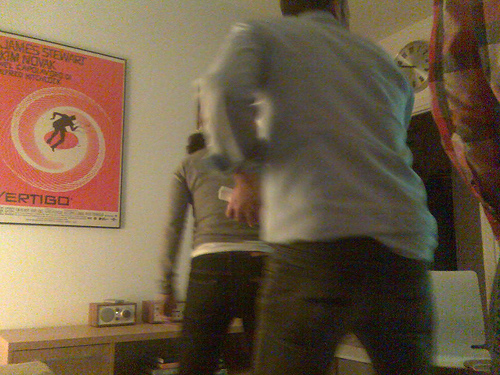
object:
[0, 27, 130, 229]
picture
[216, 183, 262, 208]
controller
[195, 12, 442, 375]
man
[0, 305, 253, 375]
desk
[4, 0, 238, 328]
wall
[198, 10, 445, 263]
shirt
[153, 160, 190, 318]
arm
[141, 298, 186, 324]
radio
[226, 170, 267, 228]
hand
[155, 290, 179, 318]
hand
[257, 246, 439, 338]
buttocks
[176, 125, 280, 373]
man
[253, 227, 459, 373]
pants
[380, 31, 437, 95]
clock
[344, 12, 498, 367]
wall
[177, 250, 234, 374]
thigh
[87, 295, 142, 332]
speaker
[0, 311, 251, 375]
stand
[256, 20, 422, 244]
back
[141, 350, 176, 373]
books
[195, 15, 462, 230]
man remote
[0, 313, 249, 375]
shelf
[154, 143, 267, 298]
sweater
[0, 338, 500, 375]
floor